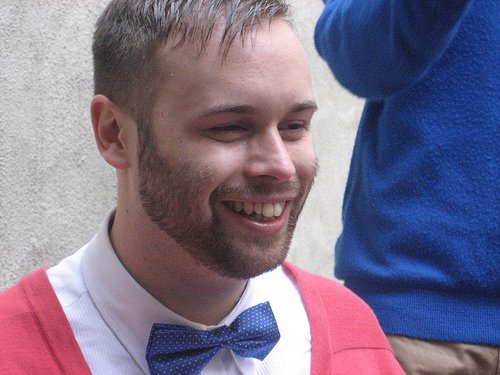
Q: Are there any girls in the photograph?
A: No, there are no girls.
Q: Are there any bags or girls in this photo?
A: No, there are no girls or bags.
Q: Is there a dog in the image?
A: No, there are no dogs.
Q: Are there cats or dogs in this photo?
A: No, there are no dogs or cats.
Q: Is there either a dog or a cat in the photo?
A: No, there are no dogs or cats.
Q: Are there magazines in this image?
A: No, there are no magazines.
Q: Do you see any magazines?
A: No, there are no magazines.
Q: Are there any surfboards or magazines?
A: No, there are no magazines or surfboards.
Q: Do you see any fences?
A: No, there are no fences.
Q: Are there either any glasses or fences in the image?
A: No, there are no fences or glasses.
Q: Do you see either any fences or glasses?
A: No, there are no fences or glasses.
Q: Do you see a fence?
A: No, there are no fences.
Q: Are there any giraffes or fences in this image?
A: No, there are no fences or giraffes.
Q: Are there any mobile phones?
A: No, there are no mobile phones.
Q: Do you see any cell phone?
A: No, there are no cell phones.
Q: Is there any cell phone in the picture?
A: No, there are no cell phones.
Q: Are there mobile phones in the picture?
A: No, there are no mobile phones.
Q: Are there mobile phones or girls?
A: No, there are no mobile phones or girls.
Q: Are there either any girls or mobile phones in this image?
A: No, there are no mobile phones or girls.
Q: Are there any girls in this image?
A: No, there are no girls.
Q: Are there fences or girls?
A: No, there are no girls or fences.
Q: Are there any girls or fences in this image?
A: No, there are no girls or fences.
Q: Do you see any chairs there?
A: No, there are no chairs.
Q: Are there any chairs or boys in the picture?
A: No, there are no chairs or boys.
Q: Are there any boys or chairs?
A: No, there are no chairs or boys.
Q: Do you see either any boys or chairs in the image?
A: No, there are no chairs or boys.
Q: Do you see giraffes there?
A: No, there are no giraffes.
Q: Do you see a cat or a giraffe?
A: No, there are no giraffes or cats.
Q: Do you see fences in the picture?
A: No, there are no fences.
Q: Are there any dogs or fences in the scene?
A: No, there are no fences or dogs.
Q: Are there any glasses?
A: No, there are no glasses.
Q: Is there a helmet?
A: No, there are no helmets.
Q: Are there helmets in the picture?
A: No, there are no helmets.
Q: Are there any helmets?
A: No, there are no helmets.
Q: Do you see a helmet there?
A: No, there are no helmets.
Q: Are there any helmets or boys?
A: No, there are no helmets or boys.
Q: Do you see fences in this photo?
A: No, there are no fences.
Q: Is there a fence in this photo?
A: No, there are no fences.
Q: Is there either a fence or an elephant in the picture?
A: No, there are no fences or elephants.